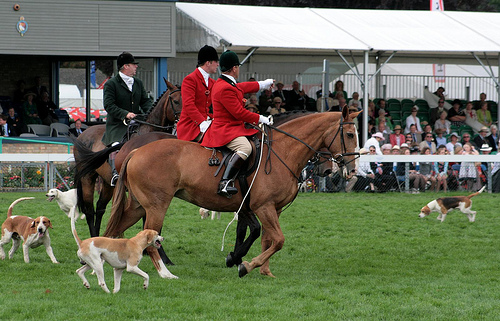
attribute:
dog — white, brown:
[1, 191, 63, 270]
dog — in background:
[413, 186, 486, 225]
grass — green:
[2, 190, 496, 319]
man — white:
[100, 50, 153, 183]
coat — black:
[102, 72, 151, 145]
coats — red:
[173, 27, 310, 199]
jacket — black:
[100, 72, 150, 144]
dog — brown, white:
[68, 202, 165, 293]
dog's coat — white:
[63, 192, 75, 207]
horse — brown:
[60, 83, 417, 274]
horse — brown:
[103, 106, 360, 276]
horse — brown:
[73, 77, 181, 237]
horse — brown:
[66, 108, 332, 262]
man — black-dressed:
[99, 49, 158, 178]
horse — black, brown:
[65, 77, 193, 263]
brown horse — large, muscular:
[98, 103, 363, 277]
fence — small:
[5, 149, 496, 187]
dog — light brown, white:
[70, 214, 163, 300]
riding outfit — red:
[204, 78, 264, 153]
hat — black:
[221, 50, 241, 70]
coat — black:
[102, 76, 152, 141]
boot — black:
[213, 144, 244, 198]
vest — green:
[477, 104, 491, 123]